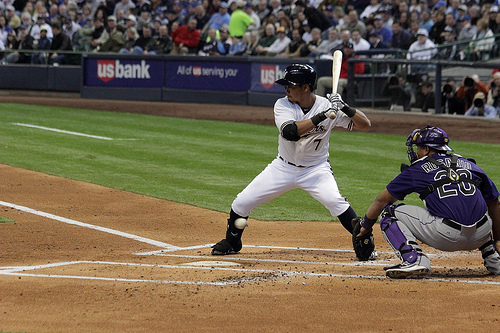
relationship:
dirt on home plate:
[1, 162, 498, 332] [181, 254, 243, 274]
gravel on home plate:
[216, 265, 283, 297] [181, 254, 243, 274]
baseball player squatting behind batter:
[353, 125, 499, 280] [235, 58, 345, 248]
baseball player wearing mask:
[353, 125, 499, 280] [403, 129, 417, 159]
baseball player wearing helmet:
[353, 125, 499, 280] [419, 122, 453, 153]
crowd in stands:
[1, 0, 493, 63] [2, 1, 499, 119]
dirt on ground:
[1, 162, 498, 332] [2, 101, 499, 332]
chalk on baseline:
[9, 192, 139, 241] [7, 169, 184, 263]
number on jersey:
[313, 137, 323, 153] [273, 95, 350, 170]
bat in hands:
[326, 42, 345, 120] [329, 89, 342, 114]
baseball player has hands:
[210, 62, 375, 260] [329, 89, 342, 114]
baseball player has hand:
[353, 125, 499, 280] [358, 221, 373, 233]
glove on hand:
[338, 216, 373, 263] [358, 221, 373, 233]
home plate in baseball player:
[180, 260, 242, 267] [210, 62, 375, 260]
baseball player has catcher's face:
[353, 125, 499, 280] [405, 135, 436, 172]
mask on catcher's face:
[398, 129, 424, 173] [405, 135, 436, 172]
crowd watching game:
[1, 0, 493, 63] [0, 31, 492, 327]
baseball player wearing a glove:
[353, 125, 499, 280] [346, 214, 381, 264]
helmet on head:
[272, 56, 327, 95] [394, 122, 450, 164]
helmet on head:
[407, 106, 462, 156] [277, 62, 323, 105]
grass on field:
[7, 99, 474, 216] [4, 84, 498, 320]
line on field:
[17, 186, 207, 266] [4, 84, 498, 320]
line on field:
[152, 231, 373, 298] [4, 84, 498, 320]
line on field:
[24, 193, 382, 327] [4, 84, 498, 320]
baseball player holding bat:
[210, 62, 375, 260] [329, 50, 344, 119]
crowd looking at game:
[1, 0, 493, 63] [0, 31, 492, 327]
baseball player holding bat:
[210, 62, 375, 260] [330, 46, 342, 119]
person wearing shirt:
[221, 0, 256, 42] [223, 10, 252, 37]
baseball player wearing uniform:
[210, 62, 375, 260] [227, 94, 355, 219]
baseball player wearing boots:
[210, 57, 382, 284] [194, 200, 383, 275]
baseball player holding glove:
[353, 125, 499, 280] [352, 216, 376, 261]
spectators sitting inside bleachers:
[1, 2, 496, 119] [1, 2, 498, 117]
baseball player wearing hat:
[210, 62, 375, 260] [266, 46, 333, 120]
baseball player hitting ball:
[210, 62, 375, 260] [233, 214, 250, 231]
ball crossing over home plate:
[235, 219, 246, 227] [178, 261, 237, 266]